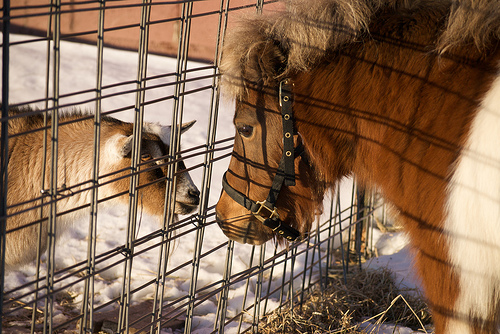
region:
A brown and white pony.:
[213, 16, 499, 332]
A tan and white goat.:
[6, 100, 198, 265]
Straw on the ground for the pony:
[262, 261, 365, 332]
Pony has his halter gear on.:
[221, 81, 305, 245]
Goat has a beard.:
[154, 214, 183, 261]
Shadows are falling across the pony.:
[236, 6, 487, 320]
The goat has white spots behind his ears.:
[95, 122, 170, 162]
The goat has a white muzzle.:
[174, 173, 199, 213]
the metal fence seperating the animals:
[3, 1, 378, 326]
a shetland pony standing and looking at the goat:
[218, 0, 499, 332]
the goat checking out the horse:
[6, 110, 196, 282]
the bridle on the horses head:
[218, 71, 310, 243]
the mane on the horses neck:
[220, 5, 499, 55]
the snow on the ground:
[16, 55, 291, 314]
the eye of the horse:
[228, 115, 255, 139]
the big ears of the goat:
[118, 120, 201, 145]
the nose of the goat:
[186, 180, 198, 198]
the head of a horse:
[183, 45, 379, 247]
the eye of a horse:
[228, 96, 288, 157]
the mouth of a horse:
[199, 203, 297, 262]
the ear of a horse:
[236, 29, 324, 102]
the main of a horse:
[221, 5, 402, 96]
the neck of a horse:
[292, 35, 479, 202]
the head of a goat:
[82, 125, 209, 251]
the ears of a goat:
[117, 98, 217, 175]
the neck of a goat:
[0, 113, 132, 230]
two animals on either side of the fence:
[0, 3, 499, 333]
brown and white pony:
[189, 0, 499, 332]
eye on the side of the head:
[236, 120, 257, 142]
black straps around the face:
[218, 68, 328, 258]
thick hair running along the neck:
[213, 0, 493, 82]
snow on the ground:
[1, 28, 396, 332]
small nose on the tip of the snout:
[186, 185, 203, 197]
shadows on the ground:
[361, 235, 423, 292]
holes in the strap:
[275, 78, 301, 163]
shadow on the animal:
[216, 212, 268, 239]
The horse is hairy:
[216, 1, 497, 332]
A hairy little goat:
[8, 106, 195, 272]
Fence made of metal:
[1, 0, 386, 332]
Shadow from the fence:
[228, 10, 495, 330]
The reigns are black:
[221, 79, 298, 240]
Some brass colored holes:
[284, 77, 291, 158]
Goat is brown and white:
[5, 105, 196, 270]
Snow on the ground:
[0, 33, 438, 333]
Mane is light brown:
[220, 1, 497, 95]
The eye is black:
[237, 124, 253, 135]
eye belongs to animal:
[235, 121, 252, 138]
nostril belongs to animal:
[214, 207, 229, 233]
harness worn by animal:
[221, 70, 311, 241]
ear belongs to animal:
[117, 134, 143, 157]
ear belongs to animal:
[167, 120, 200, 135]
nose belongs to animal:
[186, 185, 199, 196]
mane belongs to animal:
[212, 0, 499, 94]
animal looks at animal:
[4, 103, 201, 278]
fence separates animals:
[2, 2, 414, 332]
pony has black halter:
[214, 1, 498, 332]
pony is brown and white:
[213, 0, 499, 329]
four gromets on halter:
[281, 90, 293, 157]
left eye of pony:
[233, 119, 256, 139]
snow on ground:
[1, 31, 432, 332]